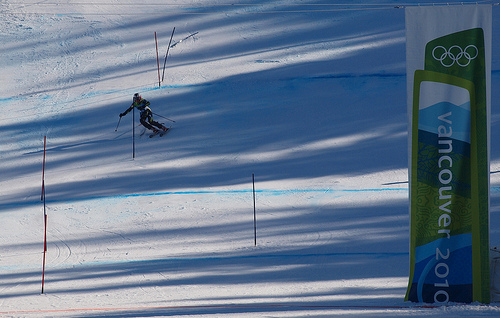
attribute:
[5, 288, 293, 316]
line — red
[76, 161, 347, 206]
marking — blue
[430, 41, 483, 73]
sign — olympic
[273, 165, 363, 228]
snow — fresh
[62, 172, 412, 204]
paint — blue